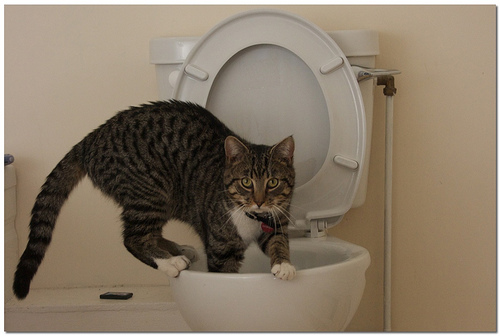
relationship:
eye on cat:
[241, 178, 253, 189] [10, 98, 307, 302]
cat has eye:
[10, 98, 307, 302] [263, 176, 279, 191]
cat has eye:
[10, 98, 307, 302] [238, 177, 257, 194]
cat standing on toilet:
[10, 98, 307, 302] [148, 14, 376, 332]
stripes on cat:
[122, 130, 197, 175] [10, 98, 307, 302]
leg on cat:
[153, 215, 197, 266] [30, 62, 364, 305]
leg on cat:
[113, 189, 187, 278] [30, 62, 364, 305]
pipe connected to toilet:
[382, 95, 394, 334] [148, 14, 376, 332]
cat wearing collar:
[13, 102, 293, 304] [239, 201, 278, 226]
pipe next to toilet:
[373, 69, 403, 334] [148, 14, 376, 332]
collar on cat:
[245, 211, 282, 229] [33, 66, 330, 292]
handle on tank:
[354, 65, 400, 80] [151, 30, 379, 209]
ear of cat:
[224, 135, 250, 158] [50, 86, 319, 315]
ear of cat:
[271, 135, 295, 164] [50, 86, 319, 315]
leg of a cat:
[263, 224, 301, 278] [77, 98, 308, 267]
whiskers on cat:
[218, 197, 302, 241] [10, 98, 307, 302]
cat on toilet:
[10, 98, 307, 302] [148, 14, 376, 332]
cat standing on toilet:
[10, 98, 307, 302] [176, 2, 341, 321]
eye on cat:
[265, 172, 280, 187] [10, 98, 307, 302]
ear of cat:
[271, 135, 295, 164] [10, 98, 307, 302]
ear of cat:
[223, 132, 251, 159] [10, 98, 307, 302]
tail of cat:
[11, 147, 90, 304] [10, 98, 307, 302]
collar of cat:
[237, 200, 288, 232] [10, 98, 307, 302]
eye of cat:
[239, 175, 251, 189] [10, 98, 307, 302]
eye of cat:
[267, 179, 278, 188] [10, 98, 307, 302]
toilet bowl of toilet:
[169, 236, 370, 333] [148, 14, 376, 332]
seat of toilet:
[164, 19, 374, 231] [141, 19, 426, 333]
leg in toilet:
[202, 244, 244, 272] [148, 14, 376, 332]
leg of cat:
[202, 244, 244, 272] [10, 98, 307, 302]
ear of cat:
[224, 135, 250, 158] [56, 92, 329, 274]